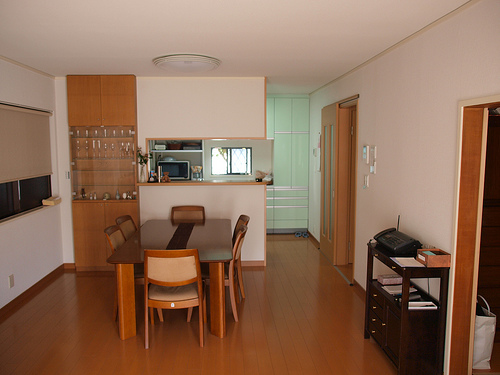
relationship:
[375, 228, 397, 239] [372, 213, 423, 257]
phone with answering machine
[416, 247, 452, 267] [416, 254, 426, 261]
box has label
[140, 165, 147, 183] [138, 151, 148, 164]
vase has flower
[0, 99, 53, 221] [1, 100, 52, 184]
window has shade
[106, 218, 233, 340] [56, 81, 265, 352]
table in kitchen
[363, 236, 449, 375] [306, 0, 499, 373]
table by wall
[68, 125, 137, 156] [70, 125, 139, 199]
glasses on shelves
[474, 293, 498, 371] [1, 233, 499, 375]
bag on floor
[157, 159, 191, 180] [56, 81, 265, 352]
microwave in kitchen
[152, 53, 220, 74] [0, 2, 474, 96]
light in ceiling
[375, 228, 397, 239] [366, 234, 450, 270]
phone on shelf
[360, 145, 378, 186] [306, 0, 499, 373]
switches on wall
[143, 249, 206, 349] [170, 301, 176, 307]
chair has spot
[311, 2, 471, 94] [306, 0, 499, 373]
edge of wall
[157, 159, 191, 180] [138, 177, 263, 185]
microwave on counter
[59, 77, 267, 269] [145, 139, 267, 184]
wall has opening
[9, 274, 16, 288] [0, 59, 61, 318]
outlet on wall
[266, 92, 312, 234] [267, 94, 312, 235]
tile on wall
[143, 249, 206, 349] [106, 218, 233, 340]
chair at table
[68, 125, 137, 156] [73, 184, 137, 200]
glasses above bar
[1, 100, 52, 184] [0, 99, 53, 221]
shade on window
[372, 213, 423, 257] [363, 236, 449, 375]
answering machine on table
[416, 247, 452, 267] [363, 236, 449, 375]
box on table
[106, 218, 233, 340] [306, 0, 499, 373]
table against wall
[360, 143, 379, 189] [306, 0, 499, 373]
frames on wall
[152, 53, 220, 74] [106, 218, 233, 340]
light above table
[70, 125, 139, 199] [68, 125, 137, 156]
shelves holding glasses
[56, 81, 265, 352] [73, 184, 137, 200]
kitchen has bar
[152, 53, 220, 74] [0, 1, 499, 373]
light in room